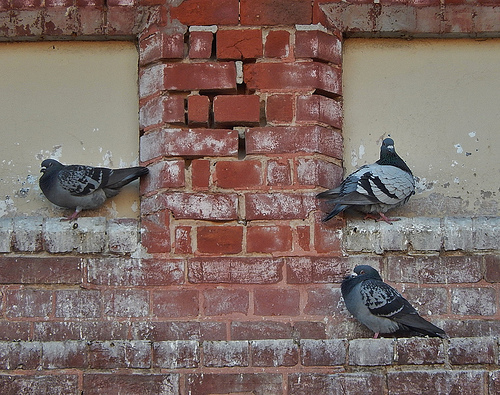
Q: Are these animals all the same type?
A: Yes, all the animals are birds.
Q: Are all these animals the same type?
A: Yes, all the animals are birds.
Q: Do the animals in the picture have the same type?
A: Yes, all the animals are birds.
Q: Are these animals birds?
A: Yes, all the animals are birds.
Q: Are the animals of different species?
A: No, all the animals are birds.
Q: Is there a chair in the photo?
A: No, there are no chairs.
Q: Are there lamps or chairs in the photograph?
A: No, there are no chairs or lamps.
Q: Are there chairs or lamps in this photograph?
A: No, there are no chairs or lamps.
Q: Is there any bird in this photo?
A: Yes, there is a bird.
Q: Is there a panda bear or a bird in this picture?
A: Yes, there is a bird.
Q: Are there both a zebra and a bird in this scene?
A: No, there is a bird but no zebras.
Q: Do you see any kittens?
A: No, there are no kittens.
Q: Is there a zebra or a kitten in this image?
A: No, there are no kittens or zebras.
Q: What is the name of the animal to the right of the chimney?
A: The animal is a bird.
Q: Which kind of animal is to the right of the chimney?
A: The animal is a bird.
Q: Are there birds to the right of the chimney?
A: Yes, there is a bird to the right of the chimney.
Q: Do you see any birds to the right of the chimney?
A: Yes, there is a bird to the right of the chimney.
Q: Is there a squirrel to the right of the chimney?
A: No, there is a bird to the right of the chimney.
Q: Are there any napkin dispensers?
A: No, there are no napkin dispensers.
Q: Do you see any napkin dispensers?
A: No, there are no napkin dispensers.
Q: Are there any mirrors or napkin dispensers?
A: No, there are no napkin dispensers or mirrors.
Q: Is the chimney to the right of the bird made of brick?
A: Yes, the chimney is made of brick.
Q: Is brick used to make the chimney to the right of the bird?
A: Yes, the chimney is made of brick.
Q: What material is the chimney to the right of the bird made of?
A: The chimney is made of brick.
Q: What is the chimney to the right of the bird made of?
A: The chimney is made of brick.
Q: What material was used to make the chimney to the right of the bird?
A: The chimney is made of brick.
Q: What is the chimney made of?
A: The chimney is made of brick.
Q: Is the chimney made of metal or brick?
A: The chimney is made of brick.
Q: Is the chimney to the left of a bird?
A: Yes, the chimney is to the left of a bird.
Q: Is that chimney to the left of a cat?
A: No, the chimney is to the left of a bird.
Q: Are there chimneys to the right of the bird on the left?
A: Yes, there is a chimney to the right of the bird.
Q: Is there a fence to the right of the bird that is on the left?
A: No, there is a chimney to the right of the bird.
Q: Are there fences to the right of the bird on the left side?
A: No, there is a chimney to the right of the bird.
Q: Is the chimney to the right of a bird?
A: Yes, the chimney is to the right of a bird.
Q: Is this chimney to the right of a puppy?
A: No, the chimney is to the right of a bird.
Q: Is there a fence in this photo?
A: No, there are no fences.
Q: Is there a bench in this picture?
A: No, there are no benches.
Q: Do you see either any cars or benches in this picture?
A: No, there are no benches or cars.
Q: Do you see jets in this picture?
A: No, there are no jets.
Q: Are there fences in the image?
A: No, there are no fences.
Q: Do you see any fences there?
A: No, there are no fences.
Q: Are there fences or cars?
A: No, there are no fences or cars.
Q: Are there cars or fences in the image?
A: No, there are no fences or cars.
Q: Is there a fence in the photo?
A: No, there are no fences.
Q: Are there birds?
A: Yes, there is a bird.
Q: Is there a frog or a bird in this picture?
A: Yes, there is a bird.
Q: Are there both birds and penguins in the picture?
A: No, there is a bird but no penguins.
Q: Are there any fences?
A: No, there are no fences.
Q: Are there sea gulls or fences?
A: No, there are no fences or sea gulls.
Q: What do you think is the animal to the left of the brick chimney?
A: The animal is a bird.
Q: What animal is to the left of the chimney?
A: The animal is a bird.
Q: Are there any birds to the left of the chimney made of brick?
A: Yes, there is a bird to the left of the chimney.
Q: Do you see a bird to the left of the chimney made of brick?
A: Yes, there is a bird to the left of the chimney.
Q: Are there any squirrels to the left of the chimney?
A: No, there is a bird to the left of the chimney.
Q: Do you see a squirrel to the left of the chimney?
A: No, there is a bird to the left of the chimney.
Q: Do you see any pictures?
A: No, there are no pictures.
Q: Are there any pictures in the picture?
A: No, there are no pictures.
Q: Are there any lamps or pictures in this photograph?
A: No, there are no pictures or lamps.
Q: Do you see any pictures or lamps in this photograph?
A: No, there are no pictures or lamps.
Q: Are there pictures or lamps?
A: No, there are no pictures or lamps.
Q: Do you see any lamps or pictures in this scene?
A: No, there are no pictures or lamps.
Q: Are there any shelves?
A: No, there are no shelves.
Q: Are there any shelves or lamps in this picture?
A: No, there are no shelves or lamps.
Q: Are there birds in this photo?
A: Yes, there is a bird.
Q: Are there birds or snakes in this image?
A: Yes, there is a bird.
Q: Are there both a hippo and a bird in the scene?
A: No, there is a bird but no hippoes.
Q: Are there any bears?
A: No, there are no bears.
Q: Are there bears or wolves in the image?
A: No, there are no bears or wolves.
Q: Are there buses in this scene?
A: No, there are no buses.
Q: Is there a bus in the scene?
A: No, there are no buses.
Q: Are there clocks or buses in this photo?
A: No, there are no buses or clocks.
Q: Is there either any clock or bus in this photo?
A: No, there are no buses or clocks.